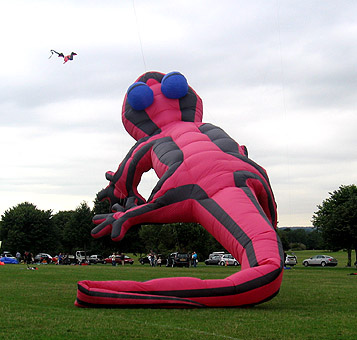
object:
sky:
[0, 0, 357, 230]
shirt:
[193, 253, 198, 260]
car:
[101, 253, 134, 266]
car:
[217, 252, 239, 266]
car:
[284, 252, 299, 266]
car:
[300, 253, 337, 266]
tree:
[309, 182, 357, 268]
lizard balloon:
[75, 70, 287, 311]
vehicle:
[169, 251, 192, 268]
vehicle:
[137, 253, 162, 266]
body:
[90, 120, 277, 242]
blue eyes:
[158, 69, 190, 101]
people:
[191, 250, 199, 268]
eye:
[125, 81, 153, 112]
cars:
[0, 250, 18, 264]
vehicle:
[203, 252, 223, 266]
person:
[14, 250, 22, 265]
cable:
[0, 295, 236, 339]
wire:
[132, 0, 147, 72]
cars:
[89, 253, 105, 265]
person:
[146, 252, 154, 267]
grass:
[0, 248, 356, 340]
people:
[54, 252, 62, 267]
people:
[118, 251, 126, 267]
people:
[110, 252, 118, 267]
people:
[156, 255, 163, 267]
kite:
[47, 48, 78, 65]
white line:
[0, 299, 41, 309]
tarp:
[0, 256, 19, 265]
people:
[57, 251, 65, 264]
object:
[21, 251, 36, 265]